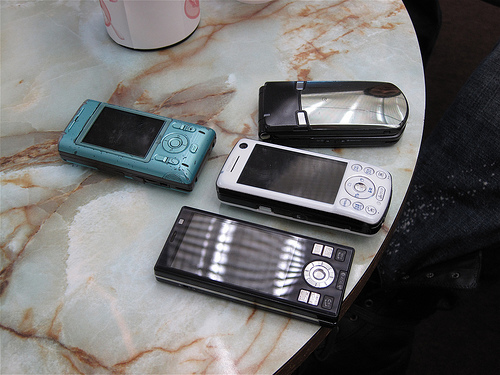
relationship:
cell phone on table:
[256, 78, 410, 149] [1, 3, 429, 374]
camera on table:
[54, 97, 218, 193] [1, 3, 429, 374]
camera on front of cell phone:
[236, 140, 248, 151] [212, 134, 393, 240]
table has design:
[1, 3, 429, 374] [3, 8, 408, 344]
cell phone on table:
[212, 134, 393, 240] [1, 3, 429, 374]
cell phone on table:
[151, 205, 355, 331] [1, 3, 429, 374]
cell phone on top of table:
[256, 78, 410, 149] [1, 3, 429, 374]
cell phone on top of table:
[212, 134, 393, 240] [1, 3, 429, 374]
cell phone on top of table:
[151, 205, 355, 331] [1, 3, 429, 374]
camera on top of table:
[54, 97, 218, 193] [1, 3, 429, 374]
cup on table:
[94, 1, 204, 52] [1, 3, 429, 374]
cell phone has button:
[151, 205, 355, 331] [308, 240, 325, 258]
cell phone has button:
[151, 205, 355, 331] [318, 245, 336, 264]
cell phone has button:
[151, 205, 355, 331] [301, 257, 336, 288]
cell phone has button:
[151, 205, 355, 331] [295, 286, 312, 304]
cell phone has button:
[151, 205, 355, 331] [306, 289, 320, 308]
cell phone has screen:
[212, 134, 393, 240] [234, 143, 348, 207]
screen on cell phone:
[234, 143, 348, 207] [212, 134, 393, 240]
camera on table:
[236, 140, 248, 151] [1, 3, 429, 374]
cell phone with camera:
[256, 78, 410, 149] [54, 97, 218, 193]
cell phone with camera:
[212, 134, 393, 240] [54, 97, 218, 193]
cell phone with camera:
[151, 205, 355, 331] [54, 97, 218, 193]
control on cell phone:
[342, 172, 376, 200] [212, 134, 393, 240]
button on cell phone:
[318, 245, 336, 264] [151, 205, 355, 331]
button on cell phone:
[306, 289, 320, 308] [151, 205, 355, 331]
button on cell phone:
[301, 257, 336, 288] [151, 205, 355, 331]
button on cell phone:
[295, 286, 312, 304] [151, 205, 355, 331]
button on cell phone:
[308, 240, 325, 258] [151, 205, 355, 331]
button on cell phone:
[349, 200, 366, 211] [212, 134, 393, 240]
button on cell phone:
[337, 196, 351, 211] [212, 134, 393, 240]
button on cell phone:
[347, 160, 361, 173] [212, 134, 393, 240]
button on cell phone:
[362, 166, 374, 176] [212, 134, 393, 240]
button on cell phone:
[374, 182, 387, 205] [212, 134, 393, 240]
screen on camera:
[77, 103, 169, 162] [54, 97, 218, 193]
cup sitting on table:
[94, 1, 204, 52] [1, 3, 429, 374]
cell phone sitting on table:
[256, 78, 410, 149] [1, 3, 429, 374]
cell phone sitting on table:
[212, 134, 393, 240] [1, 3, 429, 374]